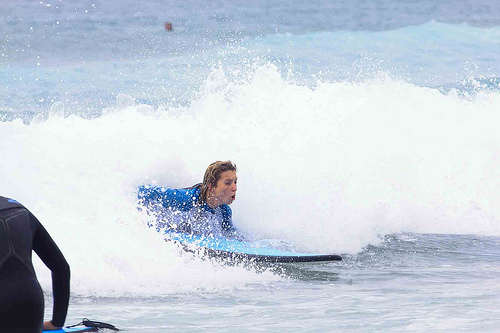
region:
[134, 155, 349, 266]
woman laying on surfboard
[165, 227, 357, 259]
blue and black surfboard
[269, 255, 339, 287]
shadow of surfboard on the water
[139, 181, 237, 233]
blue shirt of woman surfing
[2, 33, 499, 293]
wave woman is trying to surf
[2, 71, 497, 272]
white spray of the wave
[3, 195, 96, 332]
person sitting on surfboard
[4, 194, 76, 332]
black wetsuit of person sitting on surfboard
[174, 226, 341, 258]
blue top side of surfboard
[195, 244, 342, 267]
black edge of the surfboard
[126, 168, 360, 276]
woman on a surf board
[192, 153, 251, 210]
woman with blond hair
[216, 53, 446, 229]
splash of water in the ocean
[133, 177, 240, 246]
woman wearing a blue shirt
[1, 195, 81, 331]
person wearing a black wetsuit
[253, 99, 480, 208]
waves crashing in the ocean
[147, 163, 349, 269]
woman on a blue surf board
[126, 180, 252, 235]
woman in the ocean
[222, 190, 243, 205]
woman with her mouth open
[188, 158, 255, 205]
woman with wet hair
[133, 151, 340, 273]
Woman on a surfboard.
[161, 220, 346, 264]
blue surfboard on the water.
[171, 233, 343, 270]
black border on the surfboard.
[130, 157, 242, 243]
woman in a blue shirt.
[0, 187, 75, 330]
Person in a black wet suit.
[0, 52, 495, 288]
Waves in the water.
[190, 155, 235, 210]
Brown hair on the woman.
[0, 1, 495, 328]
Water in the forefront and background.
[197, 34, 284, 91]
White splashes of water.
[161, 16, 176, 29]
Brown object in the water.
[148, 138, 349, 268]
woman in surf board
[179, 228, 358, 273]
board surfer is on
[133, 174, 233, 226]
suit on the woman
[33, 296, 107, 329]
board on the water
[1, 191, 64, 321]
wet suit on person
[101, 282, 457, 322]
flat area of water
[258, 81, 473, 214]
rush of white water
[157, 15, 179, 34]
person in distance in water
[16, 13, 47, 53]
droplets of the water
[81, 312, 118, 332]
tie at end of board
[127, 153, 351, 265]
a woman on a surfboard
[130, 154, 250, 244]
woman wears blue suit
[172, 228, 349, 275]
surfboard is color blue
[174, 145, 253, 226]
surfer has short hair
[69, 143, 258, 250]
low body of woman is in the water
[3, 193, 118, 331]
surfer sits on a surfboard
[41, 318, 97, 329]
surfboard is color blue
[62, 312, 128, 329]
a black rope on surfboard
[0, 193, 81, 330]
surfer wears black suit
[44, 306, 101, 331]
a hand over surfboard